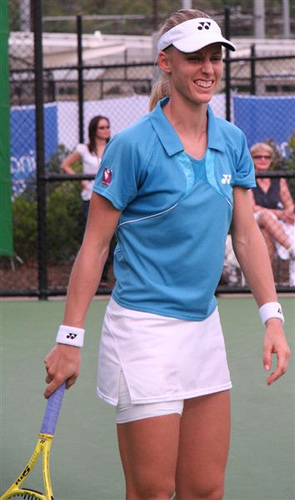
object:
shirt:
[92, 93, 258, 322]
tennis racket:
[1, 379, 65, 498]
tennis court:
[0, 294, 295, 497]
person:
[60, 116, 112, 285]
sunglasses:
[95, 125, 110, 130]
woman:
[41, 8, 292, 498]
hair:
[148, 9, 213, 117]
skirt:
[96, 298, 232, 408]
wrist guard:
[56, 324, 85, 348]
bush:
[1, 145, 117, 270]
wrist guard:
[258, 302, 284, 326]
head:
[157, 7, 223, 105]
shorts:
[115, 379, 184, 424]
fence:
[4, 0, 293, 291]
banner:
[7, 96, 295, 202]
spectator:
[224, 137, 295, 288]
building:
[8, 28, 293, 106]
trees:
[15, 144, 93, 261]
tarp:
[1, 2, 15, 259]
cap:
[157, 17, 235, 57]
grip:
[39, 383, 66, 434]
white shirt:
[77, 142, 106, 201]